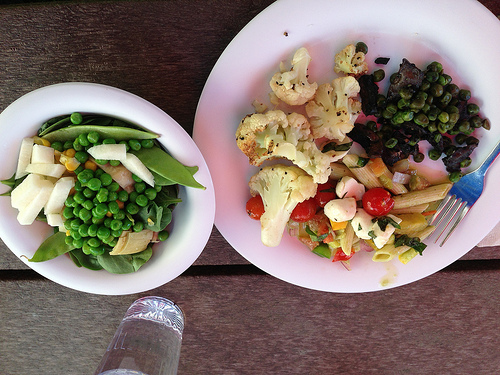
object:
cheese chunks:
[11, 174, 44, 209]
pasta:
[389, 181, 452, 210]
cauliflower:
[247, 165, 317, 246]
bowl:
[0, 80, 217, 295]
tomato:
[361, 188, 394, 217]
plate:
[194, 0, 499, 293]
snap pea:
[41, 125, 160, 143]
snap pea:
[134, 148, 207, 190]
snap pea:
[145, 162, 197, 186]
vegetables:
[85, 144, 125, 160]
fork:
[428, 145, 500, 247]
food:
[303, 76, 360, 141]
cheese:
[323, 197, 357, 223]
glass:
[93, 295, 185, 374]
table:
[0, 0, 499, 374]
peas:
[97, 227, 111, 239]